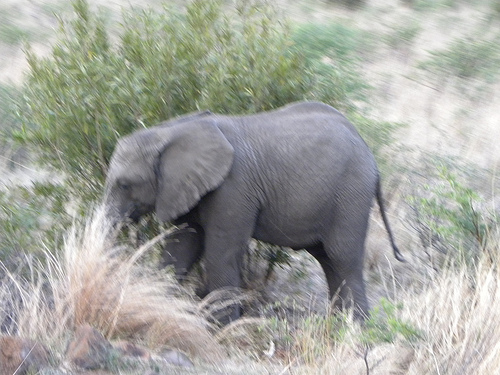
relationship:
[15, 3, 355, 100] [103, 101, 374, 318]
bush beside elephant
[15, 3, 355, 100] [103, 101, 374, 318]
bush close to elephant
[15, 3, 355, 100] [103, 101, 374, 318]
bush near elephant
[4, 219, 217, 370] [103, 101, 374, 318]
bush below elephant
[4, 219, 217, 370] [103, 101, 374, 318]
bush under elephant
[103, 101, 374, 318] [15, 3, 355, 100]
elephant close to bush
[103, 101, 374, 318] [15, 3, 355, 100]
elephant near bush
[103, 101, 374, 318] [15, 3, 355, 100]
elephant beside bush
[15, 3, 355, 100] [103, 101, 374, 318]
bush behind elephant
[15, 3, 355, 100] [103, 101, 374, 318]
bush above elephant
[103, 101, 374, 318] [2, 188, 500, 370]
elephant on ground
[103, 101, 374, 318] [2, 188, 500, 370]
elephant on top of ground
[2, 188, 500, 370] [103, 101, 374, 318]
ground below elephant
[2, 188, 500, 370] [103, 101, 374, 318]
ground under elephant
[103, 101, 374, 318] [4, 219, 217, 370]
elephant by bush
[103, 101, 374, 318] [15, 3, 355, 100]
elephant by bush